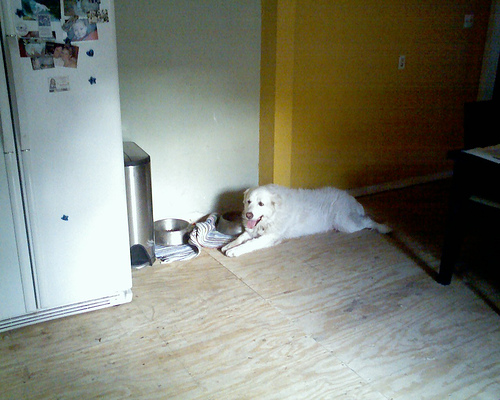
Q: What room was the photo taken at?
A: It was taken at the kitchen.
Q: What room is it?
A: It is a kitchen.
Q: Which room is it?
A: It is a kitchen.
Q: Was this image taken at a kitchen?
A: Yes, it was taken in a kitchen.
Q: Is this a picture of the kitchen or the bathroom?
A: It is showing the kitchen.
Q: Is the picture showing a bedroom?
A: No, the picture is showing a kitchen.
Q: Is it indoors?
A: Yes, it is indoors.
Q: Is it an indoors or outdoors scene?
A: It is indoors.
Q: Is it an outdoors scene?
A: No, it is indoors.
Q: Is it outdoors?
A: No, it is indoors.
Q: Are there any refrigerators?
A: Yes, there is a refrigerator.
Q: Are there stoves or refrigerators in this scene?
A: Yes, there is a refrigerator.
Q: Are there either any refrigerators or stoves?
A: Yes, there is a refrigerator.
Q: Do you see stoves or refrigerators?
A: Yes, there is a refrigerator.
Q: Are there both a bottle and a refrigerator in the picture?
A: No, there is a refrigerator but no bottles.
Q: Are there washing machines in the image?
A: No, there are no washing machines.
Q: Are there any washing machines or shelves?
A: No, there are no washing machines or shelves.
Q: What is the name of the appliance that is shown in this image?
A: The appliance is a refrigerator.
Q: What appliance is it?
A: The appliance is a refrigerator.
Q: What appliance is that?
A: This is a refrigerator.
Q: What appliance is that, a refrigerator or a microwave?
A: This is a refrigerator.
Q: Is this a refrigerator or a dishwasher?
A: This is a refrigerator.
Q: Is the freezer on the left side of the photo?
A: Yes, the freezer is on the left of the image.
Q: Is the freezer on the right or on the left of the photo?
A: The freezer is on the left of the image.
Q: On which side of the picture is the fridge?
A: The fridge is on the left of the image.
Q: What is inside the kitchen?
A: The fridge is inside the kitchen.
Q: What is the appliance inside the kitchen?
A: The appliance is a refrigerator.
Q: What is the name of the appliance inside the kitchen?
A: The appliance is a refrigerator.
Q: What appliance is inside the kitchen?
A: The appliance is a refrigerator.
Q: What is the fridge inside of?
A: The fridge is inside the kitchen.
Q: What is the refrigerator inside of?
A: The fridge is inside the kitchen.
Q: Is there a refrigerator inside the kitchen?
A: Yes, there is a refrigerator inside the kitchen.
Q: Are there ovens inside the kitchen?
A: No, there is a refrigerator inside the kitchen.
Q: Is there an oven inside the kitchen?
A: No, there is a refrigerator inside the kitchen.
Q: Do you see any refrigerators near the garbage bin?
A: Yes, there is a refrigerator near the garbage bin.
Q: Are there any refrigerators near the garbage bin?
A: Yes, there is a refrigerator near the garbage bin.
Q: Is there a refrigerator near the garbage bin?
A: Yes, there is a refrigerator near the garbage bin.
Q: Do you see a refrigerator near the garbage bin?
A: Yes, there is a refrigerator near the garbage bin.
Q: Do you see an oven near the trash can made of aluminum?
A: No, there is a refrigerator near the garbage can.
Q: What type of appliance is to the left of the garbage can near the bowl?
A: The appliance is a refrigerator.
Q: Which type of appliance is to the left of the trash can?
A: The appliance is a refrigerator.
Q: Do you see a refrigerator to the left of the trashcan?
A: Yes, there is a refrigerator to the left of the trashcan.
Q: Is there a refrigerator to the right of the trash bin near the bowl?
A: No, the refrigerator is to the left of the garbage can.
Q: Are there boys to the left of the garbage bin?
A: No, there is a refrigerator to the left of the garbage bin.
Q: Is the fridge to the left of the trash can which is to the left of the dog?
A: Yes, the fridge is to the left of the trashcan.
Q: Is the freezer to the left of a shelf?
A: No, the freezer is to the left of the trashcan.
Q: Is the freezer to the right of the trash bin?
A: No, the freezer is to the left of the trash bin.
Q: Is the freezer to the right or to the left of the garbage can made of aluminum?
A: The freezer is to the left of the trashcan.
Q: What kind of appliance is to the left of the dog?
A: The appliance is a refrigerator.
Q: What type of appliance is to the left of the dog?
A: The appliance is a refrigerator.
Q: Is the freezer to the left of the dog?
A: Yes, the freezer is to the left of the dog.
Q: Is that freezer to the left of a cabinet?
A: No, the freezer is to the left of the dog.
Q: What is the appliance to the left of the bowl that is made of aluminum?
A: The appliance is a refrigerator.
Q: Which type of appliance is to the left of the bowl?
A: The appliance is a refrigerator.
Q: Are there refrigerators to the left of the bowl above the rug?
A: Yes, there is a refrigerator to the left of the bowl.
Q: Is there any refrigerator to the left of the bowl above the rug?
A: Yes, there is a refrigerator to the left of the bowl.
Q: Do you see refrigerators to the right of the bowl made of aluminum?
A: No, the refrigerator is to the left of the bowl.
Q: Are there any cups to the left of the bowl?
A: No, there is a refrigerator to the left of the bowl.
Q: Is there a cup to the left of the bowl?
A: No, there is a refrigerator to the left of the bowl.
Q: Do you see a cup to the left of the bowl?
A: No, there is a refrigerator to the left of the bowl.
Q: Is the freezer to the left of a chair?
A: No, the freezer is to the left of the bowl.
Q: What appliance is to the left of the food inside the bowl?
A: The appliance is a refrigerator.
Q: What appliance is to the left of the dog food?
A: The appliance is a refrigerator.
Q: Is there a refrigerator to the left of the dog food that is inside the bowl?
A: Yes, there is a refrigerator to the left of the dog food.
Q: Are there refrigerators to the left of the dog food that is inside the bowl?
A: Yes, there is a refrigerator to the left of the dog food.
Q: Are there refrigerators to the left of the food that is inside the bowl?
A: Yes, there is a refrigerator to the left of the dog food.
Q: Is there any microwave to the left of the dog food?
A: No, there is a refrigerator to the left of the dog food.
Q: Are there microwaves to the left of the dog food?
A: No, there is a refrigerator to the left of the dog food.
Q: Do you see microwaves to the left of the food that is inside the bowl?
A: No, there is a refrigerator to the left of the dog food.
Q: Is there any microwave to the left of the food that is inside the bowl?
A: No, there is a refrigerator to the left of the dog food.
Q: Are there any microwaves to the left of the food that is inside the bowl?
A: No, there is a refrigerator to the left of the dog food.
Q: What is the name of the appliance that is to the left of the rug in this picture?
A: The appliance is a refrigerator.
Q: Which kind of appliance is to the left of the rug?
A: The appliance is a refrigerator.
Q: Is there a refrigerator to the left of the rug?
A: Yes, there is a refrigerator to the left of the rug.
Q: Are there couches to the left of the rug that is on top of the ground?
A: No, there is a refrigerator to the left of the rug.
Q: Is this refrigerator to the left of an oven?
A: No, the refrigerator is to the left of the rug.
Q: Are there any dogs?
A: Yes, there is a dog.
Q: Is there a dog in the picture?
A: Yes, there is a dog.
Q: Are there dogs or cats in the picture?
A: Yes, there is a dog.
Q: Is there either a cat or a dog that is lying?
A: Yes, the dog is lying.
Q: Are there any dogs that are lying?
A: Yes, there is a dog that is lying.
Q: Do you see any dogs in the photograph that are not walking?
A: Yes, there is a dog that is lying .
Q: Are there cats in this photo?
A: No, there are no cats.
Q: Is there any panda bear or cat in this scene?
A: No, there are no cats or pandas.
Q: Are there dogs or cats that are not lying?
A: No, there is a dog but it is lying.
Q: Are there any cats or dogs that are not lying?
A: No, there is a dog but it is lying.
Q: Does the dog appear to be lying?
A: Yes, the dog is lying.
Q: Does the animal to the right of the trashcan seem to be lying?
A: Yes, the dog is lying.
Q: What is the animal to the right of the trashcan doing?
A: The dog is lying.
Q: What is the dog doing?
A: The dog is lying.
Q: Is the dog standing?
A: No, the dog is lying.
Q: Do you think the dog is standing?
A: No, the dog is lying.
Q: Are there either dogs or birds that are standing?
A: No, there is a dog but it is lying.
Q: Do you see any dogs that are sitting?
A: No, there is a dog but it is lying.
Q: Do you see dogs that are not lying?
A: No, there is a dog but it is lying.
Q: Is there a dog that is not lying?
A: No, there is a dog but it is lying.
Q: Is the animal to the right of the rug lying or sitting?
A: The dog is lying.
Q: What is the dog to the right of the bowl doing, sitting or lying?
A: The dog is lying.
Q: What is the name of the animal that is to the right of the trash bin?
A: The animal is a dog.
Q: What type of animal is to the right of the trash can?
A: The animal is a dog.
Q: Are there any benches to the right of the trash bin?
A: No, there is a dog to the right of the trash bin.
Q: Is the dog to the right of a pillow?
A: No, the dog is to the right of a trash can.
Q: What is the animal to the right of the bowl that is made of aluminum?
A: The animal is a dog.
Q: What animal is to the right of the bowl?
A: The animal is a dog.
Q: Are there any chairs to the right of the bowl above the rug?
A: No, there is a dog to the right of the bowl.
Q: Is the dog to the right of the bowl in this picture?
A: Yes, the dog is to the right of the bowl.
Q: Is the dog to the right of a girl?
A: No, the dog is to the right of the bowl.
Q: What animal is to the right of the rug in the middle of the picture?
A: The animal is a dog.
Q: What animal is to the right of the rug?
A: The animal is a dog.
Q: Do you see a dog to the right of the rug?
A: Yes, there is a dog to the right of the rug.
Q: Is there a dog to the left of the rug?
A: No, the dog is to the right of the rug.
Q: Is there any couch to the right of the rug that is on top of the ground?
A: No, there is a dog to the right of the rug.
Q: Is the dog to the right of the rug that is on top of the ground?
A: Yes, the dog is to the right of the rug.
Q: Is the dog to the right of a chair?
A: No, the dog is to the right of the rug.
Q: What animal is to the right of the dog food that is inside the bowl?
A: The animal is a dog.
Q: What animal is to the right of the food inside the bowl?
A: The animal is a dog.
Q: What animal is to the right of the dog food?
A: The animal is a dog.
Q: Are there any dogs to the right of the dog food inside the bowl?
A: Yes, there is a dog to the right of the dog food.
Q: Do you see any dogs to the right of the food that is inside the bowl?
A: Yes, there is a dog to the right of the dog food.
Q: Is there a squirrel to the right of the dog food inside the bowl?
A: No, there is a dog to the right of the dog food.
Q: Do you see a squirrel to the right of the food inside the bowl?
A: No, there is a dog to the right of the dog food.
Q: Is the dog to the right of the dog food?
A: Yes, the dog is to the right of the dog food.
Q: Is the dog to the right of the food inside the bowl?
A: Yes, the dog is to the right of the dog food.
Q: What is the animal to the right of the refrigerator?
A: The animal is a dog.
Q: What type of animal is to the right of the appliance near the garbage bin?
A: The animal is a dog.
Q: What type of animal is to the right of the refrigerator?
A: The animal is a dog.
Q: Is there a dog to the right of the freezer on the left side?
A: Yes, there is a dog to the right of the refrigerator.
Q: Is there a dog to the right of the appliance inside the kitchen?
A: Yes, there is a dog to the right of the refrigerator.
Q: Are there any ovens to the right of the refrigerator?
A: No, there is a dog to the right of the refrigerator.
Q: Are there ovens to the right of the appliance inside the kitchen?
A: No, there is a dog to the right of the refrigerator.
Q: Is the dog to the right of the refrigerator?
A: Yes, the dog is to the right of the refrigerator.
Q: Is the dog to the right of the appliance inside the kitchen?
A: Yes, the dog is to the right of the refrigerator.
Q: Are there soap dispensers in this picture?
A: No, there are no soap dispensers.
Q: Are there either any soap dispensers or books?
A: No, there are no soap dispensers or books.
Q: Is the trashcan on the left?
A: Yes, the trashcan is on the left of the image.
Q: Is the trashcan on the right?
A: No, the trashcan is on the left of the image.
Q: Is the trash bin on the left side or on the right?
A: The trash bin is on the left of the image.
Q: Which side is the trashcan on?
A: The trashcan is on the left of the image.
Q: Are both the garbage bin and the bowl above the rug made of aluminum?
A: Yes, both the garbage bin and the bowl are made of aluminum.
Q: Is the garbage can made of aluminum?
A: Yes, the garbage can is made of aluminum.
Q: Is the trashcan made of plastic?
A: No, the trashcan is made of aluminum.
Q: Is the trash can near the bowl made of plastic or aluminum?
A: The trash can is made of aluminum.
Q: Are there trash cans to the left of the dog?
A: Yes, there is a trash can to the left of the dog.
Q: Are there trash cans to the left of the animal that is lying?
A: Yes, there is a trash can to the left of the dog.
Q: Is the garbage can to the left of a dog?
A: Yes, the garbage can is to the left of a dog.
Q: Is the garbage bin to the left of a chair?
A: No, the garbage bin is to the left of a dog.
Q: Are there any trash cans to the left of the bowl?
A: Yes, there is a trash can to the left of the bowl.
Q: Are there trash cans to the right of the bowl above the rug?
A: No, the trash can is to the left of the bowl.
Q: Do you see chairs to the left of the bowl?
A: No, there is a trash can to the left of the bowl.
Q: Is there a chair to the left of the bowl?
A: No, there is a trash can to the left of the bowl.